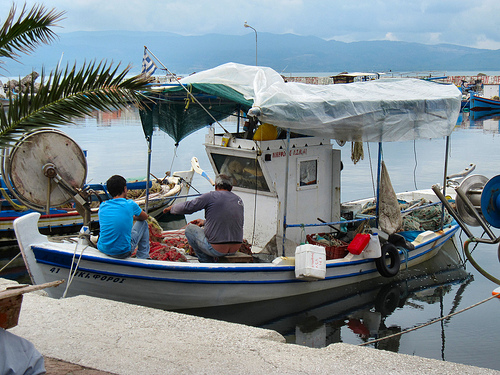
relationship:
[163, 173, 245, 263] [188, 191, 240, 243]
man has shirt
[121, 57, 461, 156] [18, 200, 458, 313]
canopy of boat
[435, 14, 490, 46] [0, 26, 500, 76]
cloud covering mountain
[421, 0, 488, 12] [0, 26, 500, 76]
cloud covering mountain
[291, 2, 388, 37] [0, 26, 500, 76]
cloud covering mountain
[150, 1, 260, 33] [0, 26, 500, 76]
cloud covering mountain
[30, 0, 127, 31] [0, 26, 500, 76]
cloud covering mountain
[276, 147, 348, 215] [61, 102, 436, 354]
window in boat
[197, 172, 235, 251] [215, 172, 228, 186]
man wearing a cap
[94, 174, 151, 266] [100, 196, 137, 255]
man wearing shirt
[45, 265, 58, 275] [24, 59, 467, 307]
number on boat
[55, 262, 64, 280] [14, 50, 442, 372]
number on boat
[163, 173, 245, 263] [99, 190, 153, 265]
man wearing shirt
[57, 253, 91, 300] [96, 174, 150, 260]
rope to left of man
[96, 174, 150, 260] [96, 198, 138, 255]
man in shirt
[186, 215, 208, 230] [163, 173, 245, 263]
hand on man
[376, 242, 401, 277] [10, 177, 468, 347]
tire on boat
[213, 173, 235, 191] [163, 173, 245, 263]
head on man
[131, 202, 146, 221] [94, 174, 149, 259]
arm on person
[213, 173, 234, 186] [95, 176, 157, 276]
cap on man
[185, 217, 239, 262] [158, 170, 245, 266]
jeans on man